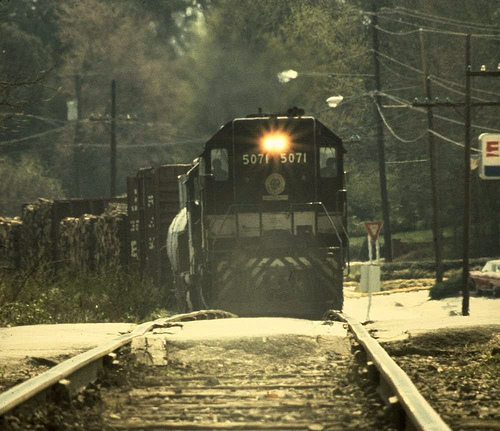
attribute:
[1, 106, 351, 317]
train — a freight train, approaching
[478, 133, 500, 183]
sign — large, for a business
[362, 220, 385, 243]
sign — a traffic sign, red, white, a yield sign, a street sign, triangular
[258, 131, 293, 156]
light — a headlight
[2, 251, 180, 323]
grass — tall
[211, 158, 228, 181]
person — train conductor, a train's conductor, engineer, conductor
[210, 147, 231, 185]
window — on the left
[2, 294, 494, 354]
road — train crossing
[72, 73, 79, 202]
utility pole — wooden, slender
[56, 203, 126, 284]
cargo — wood, pulp wood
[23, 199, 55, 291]
cargo — wood, pulp wood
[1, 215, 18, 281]
cargo — wood, pulp wood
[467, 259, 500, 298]
car — parked in lot, parked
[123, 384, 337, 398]
plank — wooden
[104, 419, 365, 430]
plank — wooden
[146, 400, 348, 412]
plank — wooden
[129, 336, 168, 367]
plank — wooden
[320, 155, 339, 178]
person — train conductor, a train's conductor, engineer, conductor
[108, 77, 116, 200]
pole — wooden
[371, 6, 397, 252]
pole — wooden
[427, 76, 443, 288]
pole — wooden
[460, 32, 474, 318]
pole — wooden